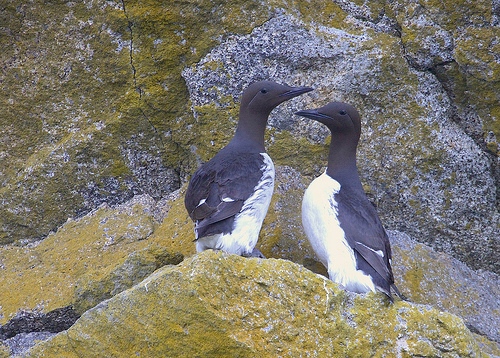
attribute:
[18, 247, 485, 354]
rocks — golden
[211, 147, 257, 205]
feather — white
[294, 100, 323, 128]
beak — black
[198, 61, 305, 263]
animal — feathered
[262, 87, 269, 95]
eyes — black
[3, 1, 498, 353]
rocks — pointed, sharp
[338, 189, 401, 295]
wings — black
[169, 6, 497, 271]
rock — speckled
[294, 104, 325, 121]
beak — black